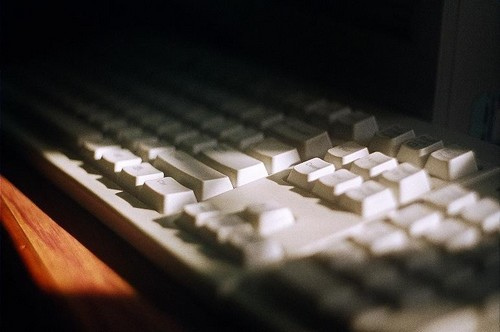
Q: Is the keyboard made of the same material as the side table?
A: No, the keyboard is made of plastic and the side table is made of wood.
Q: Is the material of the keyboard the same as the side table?
A: No, the keyboard is made of plastic and the side table is made of wood.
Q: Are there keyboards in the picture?
A: Yes, there is a keyboard.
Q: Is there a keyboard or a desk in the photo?
A: Yes, there is a keyboard.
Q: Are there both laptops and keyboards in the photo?
A: No, there is a keyboard but no laptops.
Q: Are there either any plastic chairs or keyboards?
A: Yes, there is a plastic keyboard.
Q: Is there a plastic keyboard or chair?
A: Yes, there is a plastic keyboard.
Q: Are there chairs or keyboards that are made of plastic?
A: Yes, the keyboard is made of plastic.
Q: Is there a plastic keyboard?
A: Yes, there is a keyboard that is made of plastic.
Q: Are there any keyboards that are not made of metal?
A: Yes, there is a keyboard that is made of plastic.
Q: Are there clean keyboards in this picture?
A: Yes, there is a clean keyboard.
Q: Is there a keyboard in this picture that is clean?
A: Yes, there is a clean keyboard.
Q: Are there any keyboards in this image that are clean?
A: Yes, there is a keyboard that is clean.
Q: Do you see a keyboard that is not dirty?
A: Yes, there is a clean keyboard.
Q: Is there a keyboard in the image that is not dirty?
A: Yes, there is a clean keyboard.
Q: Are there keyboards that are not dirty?
A: Yes, there is a clean keyboard.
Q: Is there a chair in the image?
A: No, there are no chairs.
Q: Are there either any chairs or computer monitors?
A: No, there are no chairs or computer monitors.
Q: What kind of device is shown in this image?
A: The device is a keyboard.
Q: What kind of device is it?
A: The device is a keyboard.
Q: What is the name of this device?
A: This is a keyboard.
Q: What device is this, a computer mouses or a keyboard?
A: This is a keyboard.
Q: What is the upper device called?
A: The device is a keyboard.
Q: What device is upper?
A: The device is a keyboard.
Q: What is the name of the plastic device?
A: The device is a keyboard.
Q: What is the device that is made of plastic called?
A: The device is a keyboard.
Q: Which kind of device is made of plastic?
A: The device is a keyboard.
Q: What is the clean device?
A: The device is a keyboard.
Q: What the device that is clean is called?
A: The device is a keyboard.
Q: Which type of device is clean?
A: The device is a keyboard.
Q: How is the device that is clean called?
A: The device is a keyboard.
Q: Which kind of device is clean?
A: The device is a keyboard.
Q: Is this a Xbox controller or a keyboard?
A: This is a keyboard.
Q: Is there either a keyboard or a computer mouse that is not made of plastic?
A: No, there is a keyboard but it is made of plastic.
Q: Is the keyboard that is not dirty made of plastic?
A: Yes, the keyboard is made of plastic.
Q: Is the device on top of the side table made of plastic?
A: Yes, the keyboard is made of plastic.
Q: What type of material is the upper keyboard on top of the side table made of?
A: The keyboard is made of plastic.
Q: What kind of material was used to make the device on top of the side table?
A: The keyboard is made of plastic.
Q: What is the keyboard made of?
A: The keyboard is made of plastic.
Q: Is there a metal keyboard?
A: No, there is a keyboard but it is made of plastic.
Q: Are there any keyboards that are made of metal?
A: No, there is a keyboard but it is made of plastic.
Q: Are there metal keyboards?
A: No, there is a keyboard but it is made of plastic.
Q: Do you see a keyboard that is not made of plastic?
A: No, there is a keyboard but it is made of plastic.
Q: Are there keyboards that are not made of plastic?
A: No, there is a keyboard but it is made of plastic.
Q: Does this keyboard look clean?
A: Yes, the keyboard is clean.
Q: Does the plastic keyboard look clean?
A: Yes, the keyboard is clean.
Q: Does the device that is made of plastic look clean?
A: Yes, the keyboard is clean.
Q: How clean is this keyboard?
A: The keyboard is clean.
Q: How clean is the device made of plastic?
A: The keyboard is clean.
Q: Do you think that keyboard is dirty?
A: No, the keyboard is clean.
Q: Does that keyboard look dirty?
A: No, the keyboard is clean.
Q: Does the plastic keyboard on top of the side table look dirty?
A: No, the keyboard is clean.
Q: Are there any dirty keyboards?
A: No, there is a keyboard but it is clean.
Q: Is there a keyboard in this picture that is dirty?
A: No, there is a keyboard but it is clean.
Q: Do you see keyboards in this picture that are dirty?
A: No, there is a keyboard but it is clean.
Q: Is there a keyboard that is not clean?
A: No, there is a keyboard but it is clean.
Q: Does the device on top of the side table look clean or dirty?
A: The keyboard is clean.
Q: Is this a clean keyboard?
A: Yes, this is a clean keyboard.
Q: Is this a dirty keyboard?
A: No, this is a clean keyboard.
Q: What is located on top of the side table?
A: The keyboard is on top of the side table.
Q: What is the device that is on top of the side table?
A: The device is a keyboard.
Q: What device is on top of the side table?
A: The device is a keyboard.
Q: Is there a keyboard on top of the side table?
A: Yes, there is a keyboard on top of the side table.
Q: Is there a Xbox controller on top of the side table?
A: No, there is a keyboard on top of the side table.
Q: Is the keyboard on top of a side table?
A: Yes, the keyboard is on top of a side table.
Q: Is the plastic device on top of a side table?
A: Yes, the keyboard is on top of a side table.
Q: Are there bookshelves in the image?
A: No, there are no bookshelves.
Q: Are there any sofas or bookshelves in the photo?
A: No, there are no bookshelves or sofas.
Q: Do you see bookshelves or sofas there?
A: No, there are no bookshelves or sofas.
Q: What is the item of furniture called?
A: The piece of furniture is a side table.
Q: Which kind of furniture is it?
A: The piece of furniture is a side table.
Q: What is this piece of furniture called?
A: This is a side table.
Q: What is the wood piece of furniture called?
A: The piece of furniture is a side table.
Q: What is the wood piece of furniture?
A: The piece of furniture is a side table.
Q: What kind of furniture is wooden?
A: The furniture is a side table.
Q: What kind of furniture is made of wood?
A: The furniture is a side table.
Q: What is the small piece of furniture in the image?
A: The piece of furniture is a side table.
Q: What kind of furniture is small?
A: The furniture is a side table.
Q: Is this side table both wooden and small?
A: Yes, the side table is wooden and small.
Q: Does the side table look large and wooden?
A: No, the side table is wooden but small.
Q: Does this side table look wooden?
A: Yes, the side table is wooden.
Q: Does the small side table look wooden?
A: Yes, the side table is wooden.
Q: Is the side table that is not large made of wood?
A: Yes, the side table is made of wood.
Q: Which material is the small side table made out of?
A: The side table is made of wood.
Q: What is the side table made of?
A: The side table is made of wood.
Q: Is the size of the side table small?
A: Yes, the side table is small.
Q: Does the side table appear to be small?
A: Yes, the side table is small.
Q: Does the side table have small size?
A: Yes, the side table is small.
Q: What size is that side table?
A: The side table is small.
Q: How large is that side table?
A: The side table is small.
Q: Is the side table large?
A: No, the side table is small.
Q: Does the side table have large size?
A: No, the side table is small.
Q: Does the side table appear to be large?
A: No, the side table is small.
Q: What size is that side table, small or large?
A: The side table is small.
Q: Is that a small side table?
A: Yes, that is a small side table.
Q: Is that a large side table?
A: No, that is a small side table.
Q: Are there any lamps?
A: No, there are no lamps.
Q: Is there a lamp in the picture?
A: No, there are no lamps.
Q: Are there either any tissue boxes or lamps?
A: No, there are no lamps or tissue boxes.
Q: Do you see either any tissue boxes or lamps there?
A: No, there are no lamps or tissue boxes.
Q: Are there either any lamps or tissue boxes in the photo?
A: No, there are no lamps or tissue boxes.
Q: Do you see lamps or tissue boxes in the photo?
A: No, there are no lamps or tissue boxes.